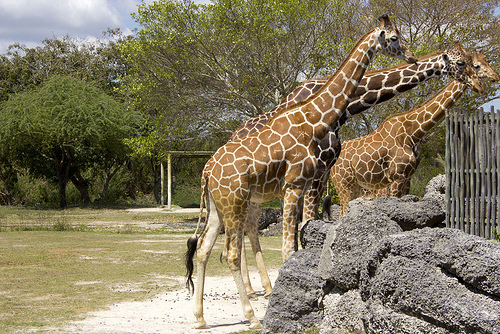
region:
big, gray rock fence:
[306, 178, 477, 331]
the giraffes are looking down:
[316, 6, 493, 206]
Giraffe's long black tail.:
[179, 237, 200, 294]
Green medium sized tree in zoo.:
[0, 73, 143, 210]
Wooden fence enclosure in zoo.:
[445, 109, 498, 234]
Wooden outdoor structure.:
[155, 146, 205, 211]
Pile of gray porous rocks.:
[267, 168, 497, 332]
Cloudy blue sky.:
[10, 2, 120, 38]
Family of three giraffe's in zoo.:
[182, 12, 499, 327]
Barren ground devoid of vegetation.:
[27, 227, 132, 324]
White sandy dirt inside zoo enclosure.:
[133, 301, 184, 332]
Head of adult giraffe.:
[377, 12, 421, 65]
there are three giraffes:
[147, 2, 492, 305]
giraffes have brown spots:
[140, 13, 480, 290]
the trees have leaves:
[51, 15, 223, 163]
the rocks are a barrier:
[310, 190, 431, 300]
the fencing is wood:
[434, 80, 491, 187]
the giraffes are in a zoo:
[184, 17, 498, 296]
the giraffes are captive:
[137, 5, 494, 314]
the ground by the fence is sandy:
[149, 260, 256, 329]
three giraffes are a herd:
[56, 10, 484, 313]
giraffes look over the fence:
[147, 13, 495, 331]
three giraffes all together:
[162, 25, 494, 332]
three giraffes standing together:
[170, 32, 492, 299]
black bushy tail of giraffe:
[171, 236, 203, 294]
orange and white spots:
[227, 130, 287, 176]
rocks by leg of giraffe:
[272, 210, 407, 313]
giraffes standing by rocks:
[167, 19, 454, 325]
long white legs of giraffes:
[183, 199, 308, 320]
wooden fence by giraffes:
[431, 106, 493, 227]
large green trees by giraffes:
[0, 75, 152, 207]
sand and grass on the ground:
[63, 254, 177, 331]